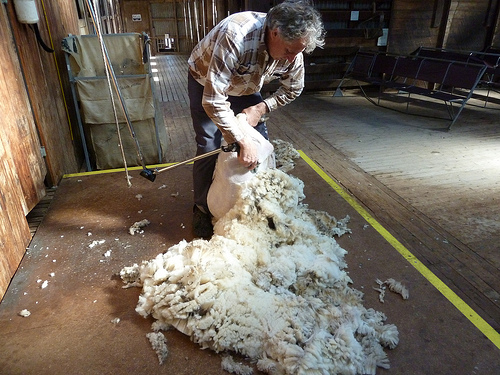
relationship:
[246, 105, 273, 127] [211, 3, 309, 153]
hand of man